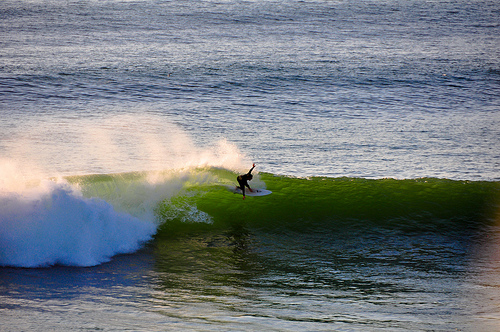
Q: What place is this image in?
A: It is at the ocean.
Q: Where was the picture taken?
A: It was taken at the ocean.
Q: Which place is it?
A: It is an ocean.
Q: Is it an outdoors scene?
A: Yes, it is outdoors.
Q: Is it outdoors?
A: Yes, it is outdoors.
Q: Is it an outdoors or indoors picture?
A: It is outdoors.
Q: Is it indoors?
A: No, it is outdoors.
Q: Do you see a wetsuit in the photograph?
A: Yes, there is a wetsuit.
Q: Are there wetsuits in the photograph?
A: Yes, there is a wetsuit.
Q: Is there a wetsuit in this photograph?
A: Yes, there is a wetsuit.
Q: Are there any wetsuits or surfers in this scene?
A: Yes, there is a wetsuit.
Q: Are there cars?
A: No, there are no cars.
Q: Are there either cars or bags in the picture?
A: No, there are no cars or bags.